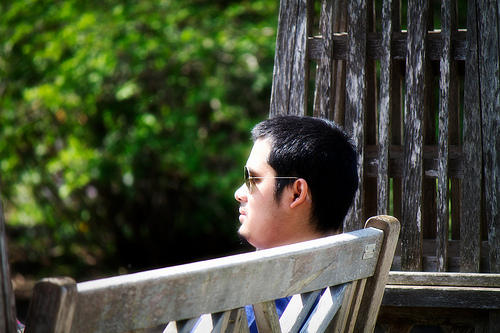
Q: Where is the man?
A: Sitting on a bench.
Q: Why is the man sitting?
A: He's resting.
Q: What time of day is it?
A: Afternoon.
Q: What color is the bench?
A: Brown.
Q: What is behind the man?
A: A tree.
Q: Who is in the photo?
A: A man.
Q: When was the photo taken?
A: Daytime.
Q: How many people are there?
A: One.